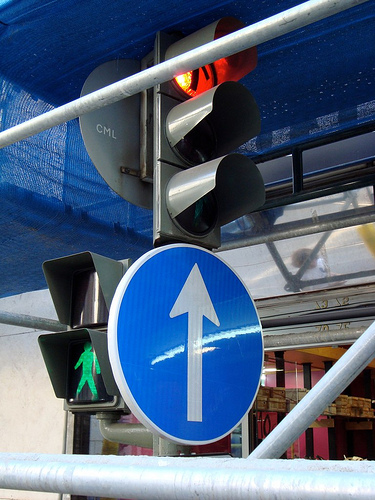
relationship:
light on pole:
[163, 15, 257, 97] [151, 433, 191, 456]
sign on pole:
[134, 240, 230, 311] [123, 224, 229, 466]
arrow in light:
[185, 61, 217, 93] [165, 40, 220, 95]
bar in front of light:
[0, 1, 370, 150] [166, 62, 223, 97]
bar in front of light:
[253, 1, 370, 47] [166, 62, 223, 97]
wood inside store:
[250, 379, 375, 424] [240, 335, 364, 453]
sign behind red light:
[49, 17, 265, 220] [174, 22, 263, 125]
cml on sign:
[96, 124, 117, 141] [77, 57, 152, 209]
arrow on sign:
[168, 262, 219, 422] [106, 241, 264, 444]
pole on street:
[0, 318, 375, 498] [0, 288, 374, 499]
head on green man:
[77, 340, 92, 352] [75, 343, 100, 403]